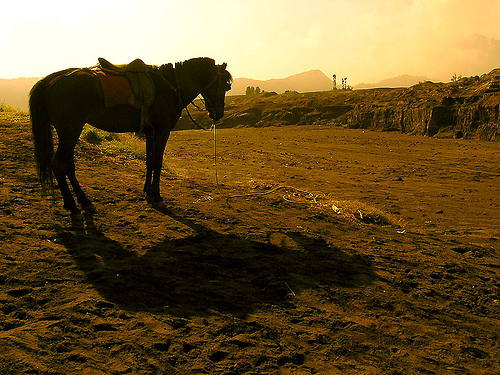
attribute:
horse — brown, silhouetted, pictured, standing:
[27, 55, 232, 212]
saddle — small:
[90, 59, 156, 137]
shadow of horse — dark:
[54, 202, 379, 318]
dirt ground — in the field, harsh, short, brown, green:
[1, 110, 499, 374]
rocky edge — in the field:
[171, 68, 500, 143]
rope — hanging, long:
[209, 125, 402, 233]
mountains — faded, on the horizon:
[227, 67, 428, 95]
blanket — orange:
[90, 64, 136, 109]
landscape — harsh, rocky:
[1, 0, 500, 374]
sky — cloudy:
[4, 1, 499, 112]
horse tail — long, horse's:
[25, 82, 61, 200]